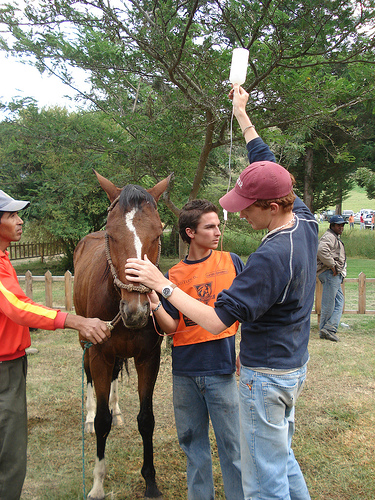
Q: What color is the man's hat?
A: Burgundy.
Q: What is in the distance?
A: Trees.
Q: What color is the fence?
A: Light brown.